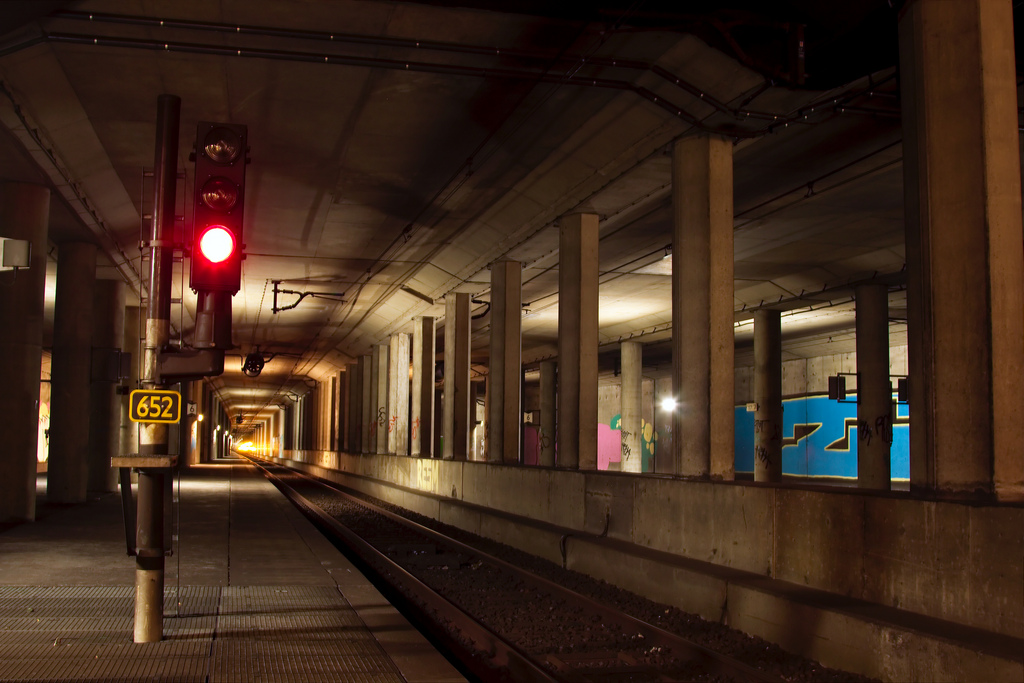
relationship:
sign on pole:
[123, 382, 186, 424] [121, 13, 176, 653]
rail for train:
[274, 449, 780, 668] [195, 382, 805, 679]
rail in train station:
[274, 449, 780, 668] [9, 6, 1021, 679]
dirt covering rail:
[249, 452, 867, 679] [274, 449, 780, 668]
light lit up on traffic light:
[199, 225, 238, 264] [176, 106, 256, 302]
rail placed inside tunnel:
[274, 449, 780, 668] [5, 7, 993, 679]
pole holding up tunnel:
[668, 124, 740, 481] [5, 7, 993, 679]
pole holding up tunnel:
[551, 210, 598, 474] [5, 7, 993, 679]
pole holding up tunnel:
[482, 255, 525, 463] [5, 7, 993, 679]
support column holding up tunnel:
[437, 290, 472, 459] [5, 7, 993, 679]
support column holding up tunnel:
[407, 305, 434, 455] [5, 7, 993, 679]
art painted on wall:
[733, 385, 913, 483] [513, 310, 915, 483]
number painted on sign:
[134, 390, 150, 416] [123, 383, 186, 425]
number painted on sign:
[147, 394, 161, 418] [123, 383, 186, 425]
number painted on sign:
[160, 392, 176, 418] [123, 383, 186, 425]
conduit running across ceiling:
[5, 31, 896, 144] [5, 3, 909, 434]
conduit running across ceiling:
[3, 5, 902, 129] [5, 3, 909, 434]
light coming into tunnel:
[229, 439, 277, 453] [5, 7, 993, 679]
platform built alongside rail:
[1, 448, 466, 678] [274, 449, 780, 668]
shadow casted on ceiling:
[234, 126, 451, 232] [5, 3, 909, 434]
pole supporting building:
[891, 3, 991, 494] [3, 3, 987, 678]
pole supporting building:
[668, 124, 740, 481] [3, 3, 987, 678]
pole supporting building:
[552, 210, 600, 474] [3, 3, 987, 678]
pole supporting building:
[482, 255, 524, 463] [3, 3, 987, 678]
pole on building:
[109, 271, 192, 643] [147, 189, 664, 546]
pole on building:
[136, 239, 273, 549] [131, 185, 615, 512]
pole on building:
[108, 271, 229, 567] [99, 166, 646, 581]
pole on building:
[717, 308, 784, 509] [713, 308, 902, 483]